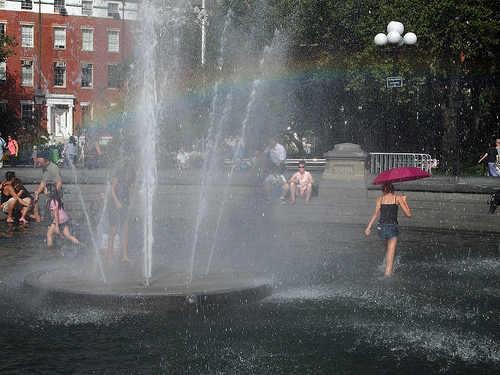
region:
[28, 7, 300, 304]
water is shooting upward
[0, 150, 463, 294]
the people are playing in the water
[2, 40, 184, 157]
a building is in the background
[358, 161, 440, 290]
the girl is holding an umbrella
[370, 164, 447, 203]
the girls umbrella is red in color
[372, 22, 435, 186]
a light is to the right of the water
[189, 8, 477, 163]
trees are in the background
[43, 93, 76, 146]
the entry way for the building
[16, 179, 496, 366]
people are enjoying the fountain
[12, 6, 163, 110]
the building has several windows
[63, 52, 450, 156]
rainbow from a reflection in the water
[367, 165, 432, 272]
woman holding an umbrella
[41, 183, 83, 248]
girl wearing pink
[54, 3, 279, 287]
fountains of spraying water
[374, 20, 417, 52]
white street lights on a pole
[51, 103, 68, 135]
white door on the building in the background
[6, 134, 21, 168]
person wearing dark pants and a pink shirt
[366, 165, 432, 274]
woman walking in the water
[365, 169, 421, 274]
woman wearing denim shorts and a black tank top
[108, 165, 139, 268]
woman wearing a black shirt and walking in the water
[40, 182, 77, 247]
a person playing in the water of a fountain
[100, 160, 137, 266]
a person playing in the water of a fountain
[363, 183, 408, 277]
a person playing in the water of a fountain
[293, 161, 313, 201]
a person sitting by a fountain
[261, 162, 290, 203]
a person sitting by a fountain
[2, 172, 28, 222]
a person sitting by a fountain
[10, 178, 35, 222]
a person sitting by a fountain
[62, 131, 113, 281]
the water stream of a fountain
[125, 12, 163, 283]
the water stream of a fountain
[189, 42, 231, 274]
the water stream of a fountain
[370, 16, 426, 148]
a tall lamp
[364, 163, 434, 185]
a large red umbrella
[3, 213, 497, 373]
a large water fountain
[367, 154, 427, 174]
a gray fence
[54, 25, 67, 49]
a window of a building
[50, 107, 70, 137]
a door of a building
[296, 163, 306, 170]
dark black sunglasses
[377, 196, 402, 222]
a woman's black tank top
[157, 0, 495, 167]
a large green tree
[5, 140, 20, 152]
a woman's pink shirt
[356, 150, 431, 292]
a woman walking with an umbrella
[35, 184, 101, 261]
a child playing in the fountain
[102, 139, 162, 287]
a girl in the middle of fountain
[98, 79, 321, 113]
a rainbow over the fountain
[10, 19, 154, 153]
a brick building behind the fountain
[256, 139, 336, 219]
people on the steps watching the fountain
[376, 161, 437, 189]
a pink umbrella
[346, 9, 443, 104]
lights in the background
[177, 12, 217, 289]
a stream of water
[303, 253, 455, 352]
a pool of water